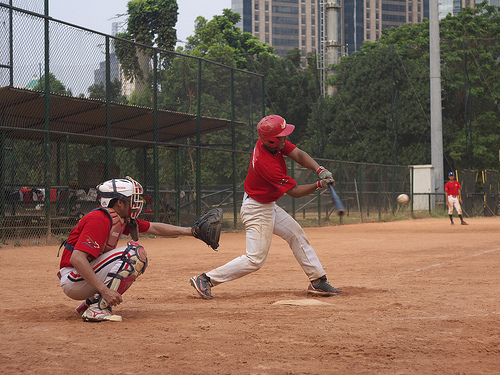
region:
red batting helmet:
[255, 113, 290, 148]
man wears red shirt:
[231, 132, 313, 199]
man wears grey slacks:
[215, 203, 313, 298]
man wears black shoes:
[302, 284, 352, 296]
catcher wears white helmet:
[99, 176, 146, 206]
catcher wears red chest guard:
[85, 203, 145, 281]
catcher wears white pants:
[53, 260, 156, 296]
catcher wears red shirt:
[75, 201, 120, 268]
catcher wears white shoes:
[81, 301, 130, 338]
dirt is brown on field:
[353, 220, 462, 368]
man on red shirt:
[224, 92, 321, 213]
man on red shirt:
[250, 102, 348, 262]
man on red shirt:
[212, 22, 339, 206]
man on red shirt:
[174, 81, 301, 191]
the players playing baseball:
[61, 114, 469, 321]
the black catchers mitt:
[193, 210, 224, 250]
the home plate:
[273, 297, 327, 304]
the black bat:
[323, 180, 344, 215]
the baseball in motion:
[398, 192, 407, 203]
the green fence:
[19, 60, 231, 198]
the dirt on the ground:
[168, 316, 334, 368]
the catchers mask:
[98, 175, 143, 218]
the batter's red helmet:
[256, 113, 293, 148]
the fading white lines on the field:
[388, 241, 498, 337]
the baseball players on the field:
[57, 113, 467, 318]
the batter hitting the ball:
[193, 112, 345, 294]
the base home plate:
[274, 296, 331, 313]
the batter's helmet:
[257, 111, 292, 147]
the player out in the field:
[444, 171, 466, 227]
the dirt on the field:
[166, 305, 353, 373]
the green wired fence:
[21, 18, 248, 216]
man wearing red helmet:
[240, 85, 327, 199]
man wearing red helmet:
[245, 80, 315, 145]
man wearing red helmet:
[231, 81, 278, 192]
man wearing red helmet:
[227, 120, 344, 264]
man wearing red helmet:
[255, 112, 376, 240]